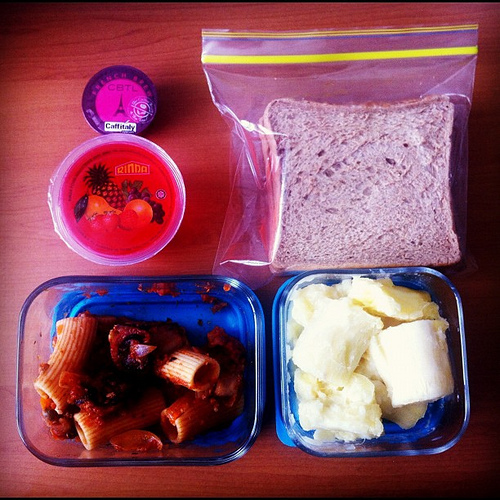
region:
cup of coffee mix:
[66, 49, 173, 146]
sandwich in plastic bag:
[210, 58, 499, 256]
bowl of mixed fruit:
[23, 173, 181, 263]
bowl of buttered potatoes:
[234, 241, 466, 450]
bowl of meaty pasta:
[28, 263, 255, 468]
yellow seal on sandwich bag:
[223, 46, 473, 265]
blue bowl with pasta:
[5, 266, 283, 481]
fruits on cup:
[73, 160, 165, 240]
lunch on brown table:
[7, 41, 487, 491]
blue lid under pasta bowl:
[28, 266, 258, 479]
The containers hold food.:
[9, 259, 469, 481]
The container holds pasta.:
[8, 263, 270, 474]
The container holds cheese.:
[267, 258, 469, 470]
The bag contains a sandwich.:
[192, 15, 487, 291]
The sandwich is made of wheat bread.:
[224, 86, 467, 283]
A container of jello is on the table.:
[37, 131, 203, 275]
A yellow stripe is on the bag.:
[190, 37, 483, 78]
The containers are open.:
[12, 252, 487, 481]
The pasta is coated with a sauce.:
[26, 274, 258, 459]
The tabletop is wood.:
[0, 2, 499, 107]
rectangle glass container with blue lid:
[18, 267, 267, 486]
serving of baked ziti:
[34, 303, 239, 456]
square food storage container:
[266, 265, 476, 460]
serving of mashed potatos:
[292, 288, 451, 440]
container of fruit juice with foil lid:
[49, 127, 185, 269]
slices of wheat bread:
[255, 80, 470, 276]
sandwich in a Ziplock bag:
[177, 17, 489, 270]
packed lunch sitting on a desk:
[14, 12, 489, 487]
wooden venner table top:
[4, 17, 78, 127]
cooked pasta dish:
[32, 309, 94, 415]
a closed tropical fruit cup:
[33, 137, 185, 264]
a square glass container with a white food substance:
[274, 278, 475, 473]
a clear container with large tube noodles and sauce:
[15, 292, 247, 476]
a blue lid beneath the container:
[229, 297, 255, 337]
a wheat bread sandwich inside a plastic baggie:
[170, 22, 496, 293]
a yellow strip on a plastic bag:
[197, 45, 490, 77]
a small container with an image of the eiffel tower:
[82, 57, 159, 139]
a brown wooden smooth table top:
[139, 28, 182, 63]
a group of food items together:
[24, 13, 495, 487]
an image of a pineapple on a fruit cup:
[80, 161, 124, 211]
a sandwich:
[334, 97, 499, 237]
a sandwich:
[275, 102, 345, 211]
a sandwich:
[249, 120, 332, 251]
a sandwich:
[293, 184, 411, 301]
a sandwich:
[260, 67, 403, 276]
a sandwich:
[271, 130, 367, 309]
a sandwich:
[281, 117, 456, 373]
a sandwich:
[209, 79, 296, 177]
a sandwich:
[237, 125, 337, 341]